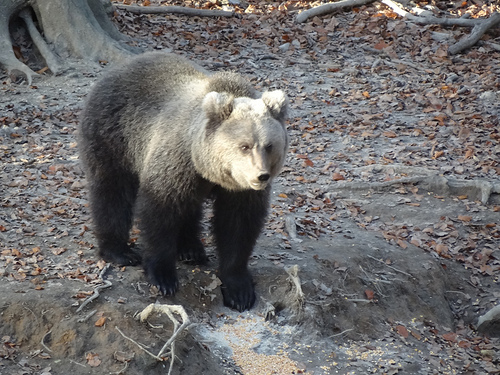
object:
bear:
[75, 51, 288, 314]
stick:
[137, 300, 192, 373]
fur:
[215, 75, 251, 95]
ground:
[1, 296, 216, 370]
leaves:
[291, 38, 308, 52]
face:
[225, 123, 279, 192]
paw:
[220, 267, 256, 313]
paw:
[143, 256, 179, 297]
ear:
[202, 89, 234, 120]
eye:
[241, 145, 249, 150]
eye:
[264, 143, 272, 153]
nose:
[258, 172, 270, 182]